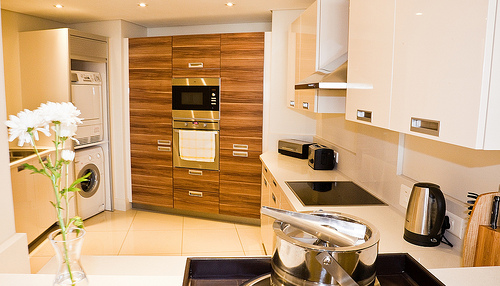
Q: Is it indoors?
A: Yes, it is indoors.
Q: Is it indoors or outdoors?
A: It is indoors.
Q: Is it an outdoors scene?
A: No, it is indoors.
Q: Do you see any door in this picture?
A: Yes, there is a door.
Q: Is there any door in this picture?
A: Yes, there is a door.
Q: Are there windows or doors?
A: Yes, there is a door.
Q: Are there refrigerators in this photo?
A: No, there are no refrigerators.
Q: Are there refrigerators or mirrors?
A: No, there are no refrigerators or mirrors.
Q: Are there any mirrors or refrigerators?
A: No, there are no refrigerators or mirrors.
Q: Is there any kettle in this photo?
A: Yes, there is a kettle.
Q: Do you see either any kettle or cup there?
A: Yes, there is a kettle.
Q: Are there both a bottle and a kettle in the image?
A: No, there is a kettle but no bottles.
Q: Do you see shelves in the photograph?
A: No, there are no shelves.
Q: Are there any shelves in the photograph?
A: No, there are no shelves.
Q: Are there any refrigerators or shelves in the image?
A: No, there are no shelves or refrigerators.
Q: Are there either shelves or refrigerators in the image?
A: No, there are no shelves or refrigerators.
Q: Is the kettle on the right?
A: Yes, the kettle is on the right of the image.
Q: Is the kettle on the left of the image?
A: No, the kettle is on the right of the image.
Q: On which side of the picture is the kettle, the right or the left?
A: The kettle is on the right of the image.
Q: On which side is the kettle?
A: The kettle is on the right of the image.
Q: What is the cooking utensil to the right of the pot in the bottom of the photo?
A: The cooking utensil is a kettle.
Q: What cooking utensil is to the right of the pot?
A: The cooking utensil is a kettle.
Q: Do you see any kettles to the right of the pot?
A: Yes, there is a kettle to the right of the pot.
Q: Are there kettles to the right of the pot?
A: Yes, there is a kettle to the right of the pot.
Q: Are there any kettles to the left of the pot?
A: No, the kettle is to the right of the pot.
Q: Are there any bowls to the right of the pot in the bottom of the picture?
A: No, there is a kettle to the right of the pot.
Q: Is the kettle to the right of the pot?
A: Yes, the kettle is to the right of the pot.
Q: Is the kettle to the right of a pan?
A: No, the kettle is to the right of the pot.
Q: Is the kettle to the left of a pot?
A: No, the kettle is to the right of a pot.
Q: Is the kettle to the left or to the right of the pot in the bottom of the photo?
A: The kettle is to the right of the pot.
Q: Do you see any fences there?
A: No, there are no fences.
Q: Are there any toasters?
A: Yes, there is a toaster.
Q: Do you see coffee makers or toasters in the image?
A: Yes, there is a toaster.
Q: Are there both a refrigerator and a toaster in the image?
A: No, there is a toaster but no refrigerators.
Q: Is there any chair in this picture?
A: No, there are no chairs.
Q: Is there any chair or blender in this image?
A: No, there are no chairs or blenders.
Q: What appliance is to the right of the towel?
A: The appliance is a toaster.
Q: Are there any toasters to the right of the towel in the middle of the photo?
A: Yes, there is a toaster to the right of the towel.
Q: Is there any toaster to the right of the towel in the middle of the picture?
A: Yes, there is a toaster to the right of the towel.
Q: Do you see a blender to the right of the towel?
A: No, there is a toaster to the right of the towel.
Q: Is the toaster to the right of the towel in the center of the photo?
A: Yes, the toaster is to the right of the towel.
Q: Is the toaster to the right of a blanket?
A: No, the toaster is to the right of the towel.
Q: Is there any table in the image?
A: Yes, there is a table.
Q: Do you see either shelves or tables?
A: Yes, there is a table.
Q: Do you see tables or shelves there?
A: Yes, there is a table.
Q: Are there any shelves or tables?
A: Yes, there is a table.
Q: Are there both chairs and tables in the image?
A: No, there is a table but no chairs.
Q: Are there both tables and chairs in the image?
A: No, there is a table but no chairs.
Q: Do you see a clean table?
A: Yes, there is a clean table.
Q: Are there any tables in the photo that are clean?
A: Yes, there is a table that is clean.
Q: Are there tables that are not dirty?
A: Yes, there is a clean table.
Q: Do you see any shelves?
A: No, there are no shelves.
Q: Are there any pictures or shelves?
A: No, there are no shelves or pictures.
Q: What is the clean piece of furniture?
A: The piece of furniture is a table.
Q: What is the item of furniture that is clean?
A: The piece of furniture is a table.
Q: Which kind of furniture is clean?
A: The furniture is a table.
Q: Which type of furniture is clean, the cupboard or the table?
A: The table is clean.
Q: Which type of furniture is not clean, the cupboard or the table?
A: The cupboard is not clean.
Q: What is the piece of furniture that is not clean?
A: The piece of furniture is a cupboard.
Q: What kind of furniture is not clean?
A: The furniture is a cupboard.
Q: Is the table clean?
A: Yes, the table is clean.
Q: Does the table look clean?
A: Yes, the table is clean.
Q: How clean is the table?
A: The table is clean.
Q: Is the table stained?
A: No, the table is clean.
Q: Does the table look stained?
A: No, the table is clean.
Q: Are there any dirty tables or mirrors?
A: No, there is a table but it is clean.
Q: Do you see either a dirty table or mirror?
A: No, there is a table but it is clean.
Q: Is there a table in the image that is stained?
A: No, there is a table but it is clean.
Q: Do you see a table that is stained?
A: No, there is a table but it is clean.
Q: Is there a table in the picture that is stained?
A: No, there is a table but it is clean.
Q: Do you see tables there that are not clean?
A: No, there is a table but it is clean.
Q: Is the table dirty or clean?
A: The table is clean.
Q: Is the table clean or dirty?
A: The table is clean.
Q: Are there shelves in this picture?
A: No, there are no shelves.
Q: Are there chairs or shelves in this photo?
A: No, there are no shelves or chairs.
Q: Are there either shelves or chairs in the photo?
A: No, there are no shelves or chairs.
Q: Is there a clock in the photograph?
A: No, there are no clocks.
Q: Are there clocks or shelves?
A: No, there are no clocks or shelves.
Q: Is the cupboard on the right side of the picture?
A: Yes, the cupboard is on the right of the image.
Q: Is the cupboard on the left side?
A: No, the cupboard is on the right of the image.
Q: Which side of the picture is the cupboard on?
A: The cupboard is on the right of the image.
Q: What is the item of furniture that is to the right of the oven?
A: The piece of furniture is a cupboard.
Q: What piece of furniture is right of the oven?
A: The piece of furniture is a cupboard.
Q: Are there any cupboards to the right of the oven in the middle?
A: Yes, there is a cupboard to the right of the oven.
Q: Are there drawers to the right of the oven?
A: No, there is a cupboard to the right of the oven.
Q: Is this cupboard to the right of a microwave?
A: No, the cupboard is to the right of the oven.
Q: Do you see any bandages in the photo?
A: No, there are no bandages.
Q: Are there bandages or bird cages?
A: No, there are no bandages or bird cages.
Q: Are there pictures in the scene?
A: No, there are no pictures.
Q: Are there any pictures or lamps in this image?
A: No, there are no pictures or lamps.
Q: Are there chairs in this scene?
A: No, there are no chairs.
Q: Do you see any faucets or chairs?
A: No, there are no chairs or faucets.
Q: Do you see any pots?
A: Yes, there is a pot.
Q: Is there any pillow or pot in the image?
A: Yes, there is a pot.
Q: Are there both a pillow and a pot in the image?
A: No, there is a pot but no pillows.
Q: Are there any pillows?
A: No, there are no pillows.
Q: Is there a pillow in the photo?
A: No, there are no pillows.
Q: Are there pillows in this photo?
A: No, there are no pillows.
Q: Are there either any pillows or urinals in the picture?
A: No, there are no pillows or urinals.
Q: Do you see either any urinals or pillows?
A: No, there are no pillows or urinals.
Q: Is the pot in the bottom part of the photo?
A: Yes, the pot is in the bottom of the image.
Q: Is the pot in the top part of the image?
A: No, the pot is in the bottom of the image.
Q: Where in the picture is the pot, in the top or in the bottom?
A: The pot is in the bottom of the image.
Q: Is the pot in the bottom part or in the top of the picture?
A: The pot is in the bottom of the image.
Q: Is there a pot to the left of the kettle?
A: Yes, there is a pot to the left of the kettle.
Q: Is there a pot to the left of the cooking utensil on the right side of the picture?
A: Yes, there is a pot to the left of the kettle.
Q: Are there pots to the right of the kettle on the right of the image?
A: No, the pot is to the left of the kettle.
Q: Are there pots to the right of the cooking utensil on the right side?
A: No, the pot is to the left of the kettle.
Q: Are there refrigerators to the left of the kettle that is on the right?
A: No, there is a pot to the left of the kettle.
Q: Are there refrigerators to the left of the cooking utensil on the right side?
A: No, there is a pot to the left of the kettle.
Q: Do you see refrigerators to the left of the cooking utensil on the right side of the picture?
A: No, there is a pot to the left of the kettle.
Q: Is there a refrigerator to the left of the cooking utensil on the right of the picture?
A: No, there is a pot to the left of the kettle.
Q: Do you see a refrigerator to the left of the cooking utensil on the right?
A: No, there is a pot to the left of the kettle.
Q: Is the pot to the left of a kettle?
A: Yes, the pot is to the left of a kettle.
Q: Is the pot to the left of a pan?
A: No, the pot is to the left of a kettle.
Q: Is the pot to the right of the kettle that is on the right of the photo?
A: No, the pot is to the left of the kettle.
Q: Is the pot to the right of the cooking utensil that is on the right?
A: No, the pot is to the left of the kettle.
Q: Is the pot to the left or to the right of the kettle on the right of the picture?
A: The pot is to the left of the kettle.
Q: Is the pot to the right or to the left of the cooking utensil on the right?
A: The pot is to the left of the kettle.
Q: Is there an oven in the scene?
A: Yes, there is an oven.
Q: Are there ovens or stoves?
A: Yes, there is an oven.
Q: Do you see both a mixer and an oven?
A: No, there is an oven but no mixers.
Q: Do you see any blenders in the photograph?
A: No, there are no blenders.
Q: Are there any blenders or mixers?
A: No, there are no blenders or mixers.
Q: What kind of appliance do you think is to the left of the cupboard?
A: The appliance is an oven.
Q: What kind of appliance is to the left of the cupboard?
A: The appliance is an oven.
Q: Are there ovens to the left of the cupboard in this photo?
A: Yes, there is an oven to the left of the cupboard.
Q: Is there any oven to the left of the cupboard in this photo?
A: Yes, there is an oven to the left of the cupboard.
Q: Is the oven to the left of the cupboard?
A: Yes, the oven is to the left of the cupboard.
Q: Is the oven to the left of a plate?
A: No, the oven is to the left of the cupboard.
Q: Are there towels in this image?
A: Yes, there is a towel.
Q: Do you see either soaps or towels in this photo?
A: Yes, there is a towel.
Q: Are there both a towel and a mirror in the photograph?
A: No, there is a towel but no mirrors.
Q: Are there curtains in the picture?
A: No, there are no curtains.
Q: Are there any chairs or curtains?
A: No, there are no curtains or chairs.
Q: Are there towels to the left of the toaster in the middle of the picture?
A: Yes, there is a towel to the left of the toaster.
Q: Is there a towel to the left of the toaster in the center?
A: Yes, there is a towel to the left of the toaster.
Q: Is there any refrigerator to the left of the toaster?
A: No, there is a towel to the left of the toaster.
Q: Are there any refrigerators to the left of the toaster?
A: No, there is a towel to the left of the toaster.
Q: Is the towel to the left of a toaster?
A: Yes, the towel is to the left of a toaster.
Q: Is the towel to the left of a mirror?
A: No, the towel is to the left of a toaster.